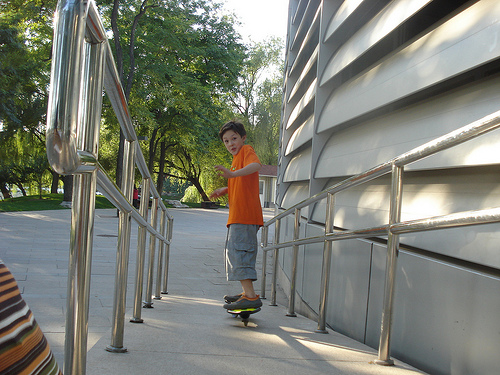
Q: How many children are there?
A: One.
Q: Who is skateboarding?
A: The boy.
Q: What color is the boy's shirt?
A: Orange.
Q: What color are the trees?
A: Green.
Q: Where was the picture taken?
A: Daytime.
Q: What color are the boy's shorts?
A: Gray.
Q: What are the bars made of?
A: Metal.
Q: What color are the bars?
A: Silver.